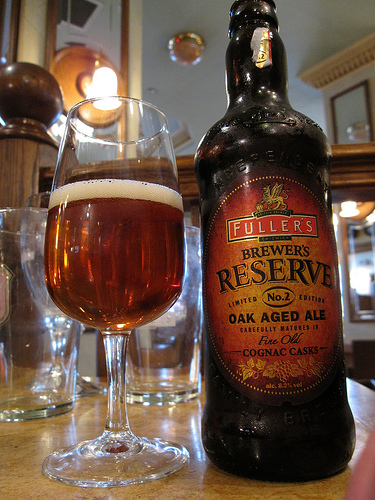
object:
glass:
[44, 96, 187, 489]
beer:
[44, 177, 186, 332]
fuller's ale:
[215, 212, 335, 357]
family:
[202, 165, 343, 406]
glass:
[0, 206, 81, 423]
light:
[83, 65, 123, 112]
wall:
[57, 0, 374, 163]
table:
[0, 375, 374, 497]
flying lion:
[255, 179, 290, 209]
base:
[42, 431, 191, 488]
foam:
[48, 178, 184, 210]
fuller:
[228, 213, 317, 241]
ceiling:
[0, 0, 374, 163]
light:
[338, 200, 360, 218]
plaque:
[340, 200, 375, 219]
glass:
[125, 224, 203, 407]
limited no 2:
[228, 285, 325, 307]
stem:
[102, 331, 131, 436]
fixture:
[167, 31, 206, 66]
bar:
[0, 0, 374, 499]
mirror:
[44, 0, 130, 165]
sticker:
[250, 27, 274, 69]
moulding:
[297, 31, 374, 89]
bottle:
[193, 0, 356, 482]